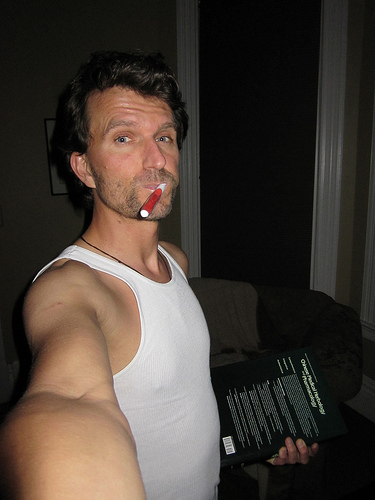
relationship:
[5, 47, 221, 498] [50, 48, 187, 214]
man has hair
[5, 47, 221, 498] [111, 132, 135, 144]
man has eye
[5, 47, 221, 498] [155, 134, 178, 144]
man has eye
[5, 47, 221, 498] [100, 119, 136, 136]
man has eyebrow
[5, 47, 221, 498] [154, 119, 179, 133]
man has eyebrow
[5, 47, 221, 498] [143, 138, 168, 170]
man has nose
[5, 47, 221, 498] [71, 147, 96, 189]
man has ear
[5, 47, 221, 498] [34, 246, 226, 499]
man has shirt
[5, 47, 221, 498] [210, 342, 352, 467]
man has book